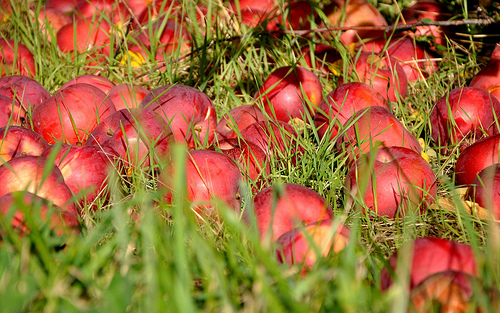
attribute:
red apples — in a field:
[346, 144, 428, 224]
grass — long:
[3, 134, 413, 310]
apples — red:
[338, 141, 442, 231]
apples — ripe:
[341, 145, 438, 221]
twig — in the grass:
[137, 19, 465, 66]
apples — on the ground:
[0, 38, 472, 311]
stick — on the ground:
[132, 22, 425, 83]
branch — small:
[115, 8, 495, 90]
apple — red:
[50, 143, 130, 213]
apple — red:
[4, 146, 73, 232]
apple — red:
[136, 78, 236, 161]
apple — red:
[378, 165, 425, 226]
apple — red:
[240, 159, 309, 246]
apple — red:
[38, 78, 110, 144]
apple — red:
[337, 133, 452, 254]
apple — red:
[339, 95, 415, 157]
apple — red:
[78, 107, 169, 182]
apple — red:
[37, 121, 134, 216]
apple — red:
[165, 78, 281, 156]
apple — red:
[314, 72, 404, 125]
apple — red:
[175, 134, 268, 255]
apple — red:
[355, 35, 465, 143]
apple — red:
[43, 15, 124, 81]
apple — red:
[244, 46, 326, 126]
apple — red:
[88, 111, 177, 182]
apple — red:
[345, 129, 429, 214]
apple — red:
[150, 135, 255, 251]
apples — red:
[4, 3, 498, 302]